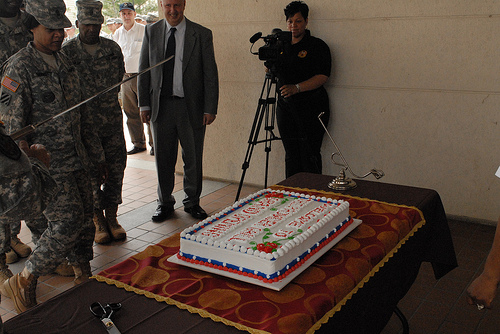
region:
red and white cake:
[175, 159, 359, 277]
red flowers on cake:
[254, 227, 286, 267]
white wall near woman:
[361, 14, 496, 136]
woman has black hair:
[273, 3, 308, 15]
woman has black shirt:
[261, 28, 339, 92]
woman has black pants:
[275, 92, 322, 164]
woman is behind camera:
[243, 25, 345, 163]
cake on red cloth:
[191, 177, 332, 288]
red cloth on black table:
[63, 179, 405, 319]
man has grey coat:
[129, 27, 221, 92]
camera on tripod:
[246, 24, 287, 181]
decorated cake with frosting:
[158, 183, 368, 288]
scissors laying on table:
[83, 291, 130, 333]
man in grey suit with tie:
[132, 0, 217, 218]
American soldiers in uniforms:
[1, 2, 126, 269]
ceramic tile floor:
[416, 296, 475, 333]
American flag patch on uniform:
[1, 73, 23, 93]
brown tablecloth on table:
[409, 182, 463, 288]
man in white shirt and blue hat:
[110, 2, 152, 152]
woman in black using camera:
[273, 0, 322, 171]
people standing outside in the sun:
[95, 5, 160, 160]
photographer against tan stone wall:
[217, 0, 492, 210]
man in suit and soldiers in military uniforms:
[5, 1, 212, 306]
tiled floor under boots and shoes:
[0, 132, 250, 312]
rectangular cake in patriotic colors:
[165, 171, 357, 281]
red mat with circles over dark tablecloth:
[85, 175, 440, 326]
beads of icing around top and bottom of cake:
[171, 160, 356, 285]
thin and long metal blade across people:
[5, 7, 175, 142]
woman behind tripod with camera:
[230, 20, 325, 195]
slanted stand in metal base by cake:
[310, 105, 381, 201]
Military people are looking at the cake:
[3, 3, 128, 313]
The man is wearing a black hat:
[110, 3, 153, 156]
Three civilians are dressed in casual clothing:
[110, 0, 327, 220]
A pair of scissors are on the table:
[86, 297, 123, 328]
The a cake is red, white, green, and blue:
[165, 186, 364, 291]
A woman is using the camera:
[235, 26, 281, 196]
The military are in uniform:
[0, 0, 125, 300]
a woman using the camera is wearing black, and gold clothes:
[260, 0, 325, 175]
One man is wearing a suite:
[135, 0, 215, 217]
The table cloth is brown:
[0, 170, 460, 331]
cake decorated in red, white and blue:
[177, 188, 352, 282]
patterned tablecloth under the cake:
[93, 184, 425, 332]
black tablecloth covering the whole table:
[0, 172, 458, 332]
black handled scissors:
[88, 298, 125, 333]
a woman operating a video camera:
[277, 2, 331, 175]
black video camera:
[249, 29, 292, 70]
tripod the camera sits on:
[232, 69, 301, 201]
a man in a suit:
[138, 0, 216, 219]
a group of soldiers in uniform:
[0, 0, 126, 312]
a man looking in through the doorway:
[112, 2, 154, 157]